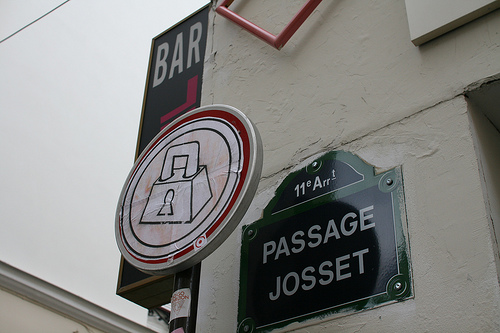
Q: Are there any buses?
A: No, there are no buses.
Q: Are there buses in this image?
A: No, there are no buses.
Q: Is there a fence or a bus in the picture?
A: No, there are no buses or fences.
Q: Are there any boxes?
A: No, there are no boxes.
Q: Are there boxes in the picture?
A: No, there are no boxes.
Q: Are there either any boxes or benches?
A: No, there are no boxes or benches.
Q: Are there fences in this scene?
A: No, there are no fences.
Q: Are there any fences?
A: No, there are no fences.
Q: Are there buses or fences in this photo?
A: No, there are no fences or buses.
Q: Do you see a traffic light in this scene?
A: No, there are no traffic lights.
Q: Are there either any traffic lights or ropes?
A: No, there are no traffic lights or ropes.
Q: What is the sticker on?
A: The sticker is on the pole.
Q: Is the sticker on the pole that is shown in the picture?
A: Yes, the sticker is on the pole.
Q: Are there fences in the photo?
A: No, there are no fences.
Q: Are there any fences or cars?
A: No, there are no fences or cars.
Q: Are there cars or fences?
A: No, there are no fences or cars.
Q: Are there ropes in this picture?
A: No, there are no ropes.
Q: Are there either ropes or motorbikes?
A: No, there are no ropes or motorbikes.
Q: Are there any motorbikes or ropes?
A: No, there are no ropes or motorbikes.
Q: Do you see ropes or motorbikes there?
A: No, there are no ropes or motorbikes.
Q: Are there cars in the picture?
A: No, there are no cars.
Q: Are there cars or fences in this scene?
A: No, there are no cars or fences.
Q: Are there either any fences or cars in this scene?
A: No, there are no cars or fences.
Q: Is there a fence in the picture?
A: No, there are no fences.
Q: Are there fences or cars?
A: No, there are no fences or cars.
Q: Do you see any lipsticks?
A: No, there are no lipsticks.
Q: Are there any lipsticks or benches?
A: No, there are no lipsticks or benches.